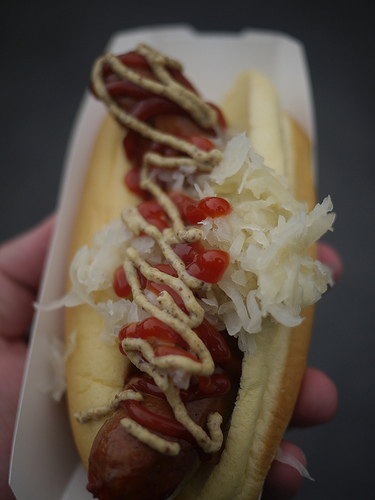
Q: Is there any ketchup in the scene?
A: Yes, there is ketchup.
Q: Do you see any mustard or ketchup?
A: Yes, there is ketchup.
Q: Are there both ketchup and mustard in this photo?
A: Yes, there are both ketchup and mustard.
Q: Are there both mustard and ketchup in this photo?
A: Yes, there are both ketchup and mustard.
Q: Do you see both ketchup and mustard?
A: Yes, there are both ketchup and mustard.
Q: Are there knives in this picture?
A: No, there are no knives.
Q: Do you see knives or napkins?
A: No, there are no knives or napkins.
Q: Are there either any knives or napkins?
A: No, there are no knives or napkins.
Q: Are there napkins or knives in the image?
A: No, there are no knives or napkins.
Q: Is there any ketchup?
A: Yes, there is ketchup.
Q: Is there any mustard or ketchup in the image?
A: Yes, there is ketchup.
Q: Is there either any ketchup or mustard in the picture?
A: Yes, there is ketchup.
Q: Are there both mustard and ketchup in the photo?
A: Yes, there are both ketchup and mustard.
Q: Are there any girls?
A: No, there are no girls.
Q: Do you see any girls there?
A: No, there are no girls.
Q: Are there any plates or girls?
A: No, there are no girls or plates.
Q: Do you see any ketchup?
A: Yes, there is ketchup.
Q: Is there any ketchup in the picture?
A: Yes, there is ketchup.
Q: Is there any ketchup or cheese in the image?
A: Yes, there is ketchup.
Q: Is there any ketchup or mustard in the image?
A: Yes, there is ketchup.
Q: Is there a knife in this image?
A: No, there are no knives.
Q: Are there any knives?
A: No, there are no knives.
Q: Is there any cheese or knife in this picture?
A: No, there are no knives or cheese.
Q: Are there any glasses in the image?
A: No, there are no glasses.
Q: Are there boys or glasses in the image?
A: No, there are no glasses or boys.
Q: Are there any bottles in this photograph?
A: No, there are no bottles.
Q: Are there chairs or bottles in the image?
A: No, there are no bottles or chairs.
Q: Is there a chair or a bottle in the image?
A: No, there are no bottles or chairs.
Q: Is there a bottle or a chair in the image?
A: No, there are no bottles or chairs.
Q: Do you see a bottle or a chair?
A: No, there are no bottles or chairs.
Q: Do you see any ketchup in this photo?
A: Yes, there is ketchup.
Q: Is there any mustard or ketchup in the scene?
A: Yes, there is ketchup.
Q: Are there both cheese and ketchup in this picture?
A: No, there is ketchup but no cheese.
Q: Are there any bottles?
A: No, there are no bottles.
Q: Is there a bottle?
A: No, there are no bottles.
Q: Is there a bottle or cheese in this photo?
A: No, there are no bottles or cheese.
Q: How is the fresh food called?
A: The food is a bun.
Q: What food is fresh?
A: The food is a bun.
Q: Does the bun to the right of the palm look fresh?
A: Yes, the bun is fresh.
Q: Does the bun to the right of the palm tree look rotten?
A: No, the bun is fresh.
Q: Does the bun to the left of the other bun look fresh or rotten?
A: The bun is fresh.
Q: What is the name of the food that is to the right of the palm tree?
A: The food is a bun.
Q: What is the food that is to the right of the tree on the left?
A: The food is a bun.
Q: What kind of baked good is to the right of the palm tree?
A: The food is a bun.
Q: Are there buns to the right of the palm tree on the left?
A: Yes, there is a bun to the right of the palm tree.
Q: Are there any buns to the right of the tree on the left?
A: Yes, there is a bun to the right of the palm tree.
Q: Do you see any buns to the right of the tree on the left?
A: Yes, there is a bun to the right of the palm tree.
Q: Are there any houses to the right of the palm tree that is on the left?
A: No, there is a bun to the right of the palm.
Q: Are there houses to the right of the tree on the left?
A: No, there is a bun to the right of the palm.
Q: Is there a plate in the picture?
A: No, there are no plates.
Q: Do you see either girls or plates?
A: No, there are no plates or girls.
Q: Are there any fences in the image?
A: No, there are no fences.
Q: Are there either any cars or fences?
A: No, there are no fences or cars.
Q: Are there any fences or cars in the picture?
A: No, there are no fences or cars.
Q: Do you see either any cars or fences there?
A: No, there are no fences or cars.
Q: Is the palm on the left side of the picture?
A: Yes, the palm is on the left of the image.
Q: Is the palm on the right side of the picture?
A: No, the palm is on the left of the image.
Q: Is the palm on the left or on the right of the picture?
A: The palm is on the left of the image.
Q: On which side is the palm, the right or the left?
A: The palm is on the left of the image.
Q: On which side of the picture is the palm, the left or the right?
A: The palm is on the left of the image.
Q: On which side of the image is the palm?
A: The palm is on the left of the image.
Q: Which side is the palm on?
A: The palm is on the left of the image.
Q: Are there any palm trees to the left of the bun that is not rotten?
A: Yes, there is a palm tree to the left of the bun.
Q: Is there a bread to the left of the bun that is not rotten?
A: No, there is a palm tree to the left of the bun.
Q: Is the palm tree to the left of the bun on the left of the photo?
A: Yes, the palm tree is to the left of the bun.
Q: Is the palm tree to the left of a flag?
A: No, the palm tree is to the left of the bun.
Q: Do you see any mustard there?
A: Yes, there is mustard.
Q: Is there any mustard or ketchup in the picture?
A: Yes, there is mustard.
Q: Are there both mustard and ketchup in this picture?
A: Yes, there are both mustard and ketchup.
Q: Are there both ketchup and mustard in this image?
A: Yes, there are both mustard and ketchup.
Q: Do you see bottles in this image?
A: No, there are no bottles.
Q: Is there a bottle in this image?
A: No, there are no bottles.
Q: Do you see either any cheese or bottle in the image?
A: No, there are no bottles or cheese.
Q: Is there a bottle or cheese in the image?
A: No, there are no bottles or cheese.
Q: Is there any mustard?
A: Yes, there is mustard.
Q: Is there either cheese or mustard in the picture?
A: Yes, there is mustard.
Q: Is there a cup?
A: No, there are no cups.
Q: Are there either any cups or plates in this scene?
A: No, there are no cups or plates.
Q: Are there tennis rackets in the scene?
A: No, there are no tennis rackets.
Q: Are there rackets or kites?
A: No, there are no rackets or kites.